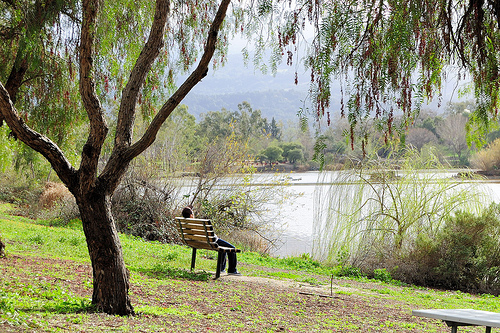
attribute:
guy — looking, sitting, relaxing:
[180, 206, 239, 278]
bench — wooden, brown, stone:
[176, 219, 242, 280]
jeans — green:
[212, 235, 242, 277]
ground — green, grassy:
[3, 208, 498, 333]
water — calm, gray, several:
[120, 167, 500, 261]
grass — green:
[3, 223, 310, 268]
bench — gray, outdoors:
[417, 300, 499, 332]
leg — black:
[214, 250, 224, 279]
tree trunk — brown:
[78, 187, 136, 311]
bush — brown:
[35, 183, 76, 223]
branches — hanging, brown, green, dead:
[306, 1, 499, 75]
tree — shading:
[70, 2, 194, 323]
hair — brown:
[185, 207, 190, 215]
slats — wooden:
[188, 226, 204, 237]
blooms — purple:
[419, 33, 437, 65]